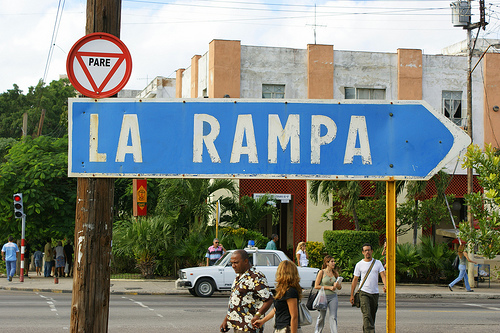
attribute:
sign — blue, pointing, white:
[61, 96, 469, 183]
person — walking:
[341, 240, 391, 331]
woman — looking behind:
[249, 257, 304, 330]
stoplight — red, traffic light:
[12, 189, 28, 226]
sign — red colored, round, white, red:
[64, 30, 134, 99]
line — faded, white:
[36, 287, 69, 328]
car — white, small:
[167, 244, 330, 298]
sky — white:
[4, 1, 499, 87]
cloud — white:
[10, 4, 493, 89]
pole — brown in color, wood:
[67, 1, 122, 331]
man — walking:
[216, 247, 272, 330]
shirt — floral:
[227, 271, 271, 330]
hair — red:
[277, 262, 299, 302]